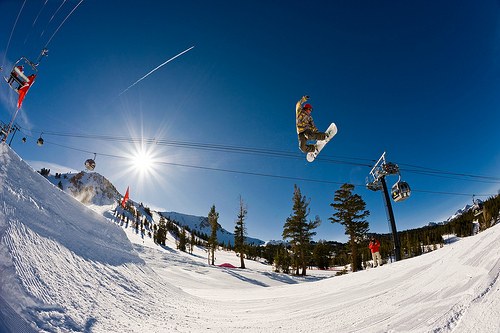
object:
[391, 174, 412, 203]
gondola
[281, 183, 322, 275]
tree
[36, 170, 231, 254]
mountain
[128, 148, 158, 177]
sun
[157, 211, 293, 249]
mountains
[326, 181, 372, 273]
tree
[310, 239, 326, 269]
tree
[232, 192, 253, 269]
tree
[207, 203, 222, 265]
tree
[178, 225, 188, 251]
tree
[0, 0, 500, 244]
blue sky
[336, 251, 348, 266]
tree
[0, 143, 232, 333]
ramp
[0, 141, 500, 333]
snow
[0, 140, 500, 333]
ground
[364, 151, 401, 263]
tower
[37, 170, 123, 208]
small mountain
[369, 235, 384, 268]
person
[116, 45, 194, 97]
contrail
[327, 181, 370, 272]
evergreen trees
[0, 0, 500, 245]
sky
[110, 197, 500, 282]
resort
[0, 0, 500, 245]
distance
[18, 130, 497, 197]
cables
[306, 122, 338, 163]
skateboarder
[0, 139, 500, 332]
half pipe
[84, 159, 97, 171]
ski lift